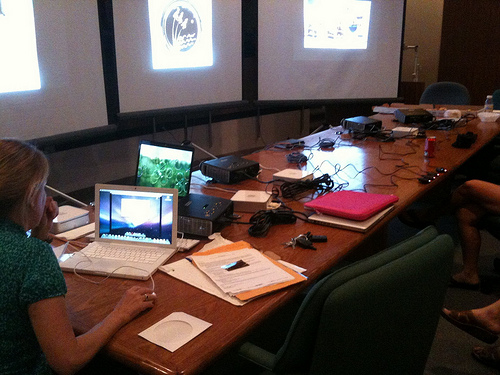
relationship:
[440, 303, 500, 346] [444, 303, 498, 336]
sandal on foot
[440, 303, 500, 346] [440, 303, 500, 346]
sole on sandal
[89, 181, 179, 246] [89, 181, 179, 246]
monitor on monitor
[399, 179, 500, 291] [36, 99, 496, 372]
person at table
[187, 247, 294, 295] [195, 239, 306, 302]
paper on top of folder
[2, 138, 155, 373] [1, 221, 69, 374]
woman wearing green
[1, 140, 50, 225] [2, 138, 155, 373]
blonde haired woman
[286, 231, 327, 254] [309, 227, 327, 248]
key chain fob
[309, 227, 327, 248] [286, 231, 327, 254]
fob on a key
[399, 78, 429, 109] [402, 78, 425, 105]
edge of a table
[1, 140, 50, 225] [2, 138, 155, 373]
hair of a woman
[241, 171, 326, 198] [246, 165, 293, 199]
portion of a cable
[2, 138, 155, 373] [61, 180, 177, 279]
girl using a laptop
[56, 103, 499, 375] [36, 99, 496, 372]
large conference table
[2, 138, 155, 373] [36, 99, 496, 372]
woman at table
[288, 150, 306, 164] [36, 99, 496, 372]
gadget on top of table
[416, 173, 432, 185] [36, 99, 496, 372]
gadget on top of table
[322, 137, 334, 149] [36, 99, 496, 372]
gadget on top of table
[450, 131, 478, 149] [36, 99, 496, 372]
gadget on top of table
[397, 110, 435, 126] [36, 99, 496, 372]
gadget on top of table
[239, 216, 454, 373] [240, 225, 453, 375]
empty green chair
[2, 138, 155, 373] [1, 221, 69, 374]
girl wearing green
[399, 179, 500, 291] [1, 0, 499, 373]
person in room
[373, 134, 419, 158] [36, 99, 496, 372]
wire on top of table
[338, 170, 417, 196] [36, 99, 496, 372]
wire on top of table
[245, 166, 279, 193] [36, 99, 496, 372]
wire on top of table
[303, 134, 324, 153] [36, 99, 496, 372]
wire on top of table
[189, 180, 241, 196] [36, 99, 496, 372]
wire on top of table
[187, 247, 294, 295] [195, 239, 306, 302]
paper on top of an envelope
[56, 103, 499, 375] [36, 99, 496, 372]
brown wooden table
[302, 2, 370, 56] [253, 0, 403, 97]
image on screen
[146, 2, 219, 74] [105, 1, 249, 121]
image on a screen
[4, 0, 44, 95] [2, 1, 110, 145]
image on a screen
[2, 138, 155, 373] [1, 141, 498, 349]
woman at a meeting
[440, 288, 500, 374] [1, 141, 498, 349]
woman at a meeting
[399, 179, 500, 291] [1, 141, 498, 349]
woman at a meeting